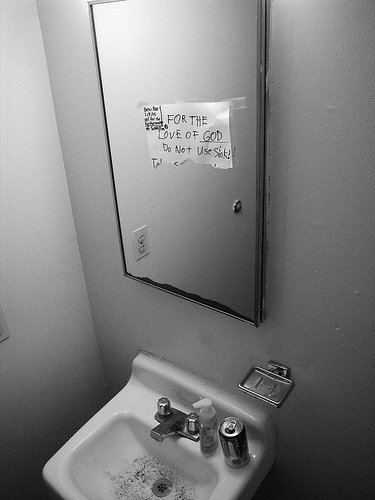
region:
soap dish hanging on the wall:
[231, 356, 307, 409]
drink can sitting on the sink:
[216, 411, 252, 473]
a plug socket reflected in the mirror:
[129, 220, 156, 265]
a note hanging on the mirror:
[128, 90, 254, 175]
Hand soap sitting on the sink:
[187, 391, 220, 457]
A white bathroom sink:
[37, 342, 315, 497]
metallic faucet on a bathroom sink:
[149, 386, 201, 449]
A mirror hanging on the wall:
[80, 2, 298, 334]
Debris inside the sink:
[120, 448, 195, 498]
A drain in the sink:
[146, 472, 178, 497]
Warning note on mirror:
[125, 93, 253, 183]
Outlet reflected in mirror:
[117, 219, 157, 265]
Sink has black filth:
[110, 456, 189, 498]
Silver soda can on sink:
[216, 410, 252, 469]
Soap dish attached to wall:
[222, 353, 299, 406]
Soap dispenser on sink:
[184, 391, 215, 454]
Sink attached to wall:
[35, 332, 303, 498]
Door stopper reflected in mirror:
[219, 186, 249, 231]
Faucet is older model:
[148, 392, 203, 445]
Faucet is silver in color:
[140, 392, 218, 450]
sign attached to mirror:
[134, 91, 245, 181]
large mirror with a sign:
[97, 44, 285, 340]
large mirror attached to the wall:
[85, 2, 273, 337]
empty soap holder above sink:
[237, 354, 307, 408]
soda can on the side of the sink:
[216, 413, 248, 473]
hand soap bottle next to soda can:
[188, 392, 222, 458]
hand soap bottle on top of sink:
[185, 393, 220, 459]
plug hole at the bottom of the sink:
[146, 477, 184, 499]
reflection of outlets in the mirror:
[127, 227, 168, 270]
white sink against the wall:
[39, 339, 273, 496]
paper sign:
[136, 90, 260, 183]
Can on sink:
[214, 409, 254, 470]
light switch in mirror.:
[117, 217, 153, 268]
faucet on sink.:
[137, 399, 202, 453]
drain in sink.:
[149, 463, 179, 498]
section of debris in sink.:
[129, 453, 180, 471]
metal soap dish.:
[231, 357, 302, 424]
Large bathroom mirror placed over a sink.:
[83, 0, 276, 336]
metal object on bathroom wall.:
[228, 199, 247, 218]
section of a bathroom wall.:
[18, 161, 44, 203]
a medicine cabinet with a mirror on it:
[82, 3, 302, 328]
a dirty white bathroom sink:
[34, 348, 285, 498]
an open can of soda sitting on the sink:
[214, 401, 258, 476]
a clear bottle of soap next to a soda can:
[185, 383, 223, 467]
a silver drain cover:
[144, 467, 184, 498]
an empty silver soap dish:
[235, 351, 300, 411]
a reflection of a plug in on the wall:
[122, 226, 160, 274]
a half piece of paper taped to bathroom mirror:
[133, 87, 254, 185]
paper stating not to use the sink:
[133, 84, 248, 183]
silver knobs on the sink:
[144, 390, 212, 467]